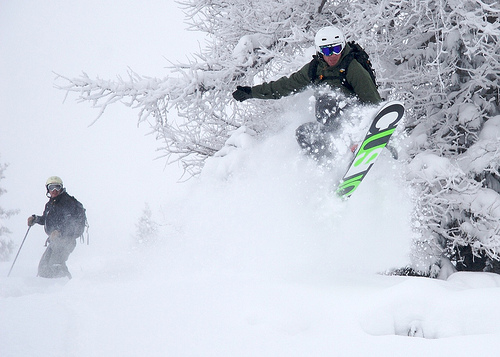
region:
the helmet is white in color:
[305, 24, 348, 58]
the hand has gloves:
[226, 78, 258, 109]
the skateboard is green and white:
[319, 107, 409, 209]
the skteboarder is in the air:
[219, 30, 414, 197]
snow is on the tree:
[391, 13, 484, 144]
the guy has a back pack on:
[40, 200, 98, 236]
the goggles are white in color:
[308, 41, 348, 68]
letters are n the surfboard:
[360, 104, 402, 189]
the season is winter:
[6, 8, 483, 350]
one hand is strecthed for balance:
[207, 34, 417, 199]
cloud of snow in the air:
[85, 87, 413, 327]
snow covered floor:
[0, 275, 496, 352]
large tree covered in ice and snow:
[56, 2, 498, 270]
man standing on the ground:
[10, 173, 90, 283]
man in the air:
[233, 28, 378, 168]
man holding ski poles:
[4, 177, 91, 281]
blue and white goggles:
[319, 44, 342, 54]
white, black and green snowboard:
[334, 102, 402, 204]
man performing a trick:
[233, 29, 378, 165]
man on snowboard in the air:
[230, 28, 402, 205]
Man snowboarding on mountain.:
[231, 21, 406, 206]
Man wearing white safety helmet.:
[311, 20, 349, 44]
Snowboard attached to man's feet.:
[335, 99, 406, 206]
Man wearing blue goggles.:
[318, 42, 349, 57]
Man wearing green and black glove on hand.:
[230, 83, 257, 100]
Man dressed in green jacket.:
[251, 42, 383, 103]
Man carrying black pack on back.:
[346, 37, 379, 87]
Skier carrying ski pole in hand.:
[4, 214, 39, 284]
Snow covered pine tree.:
[423, 16, 498, 268]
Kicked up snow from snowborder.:
[257, 87, 399, 263]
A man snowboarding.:
[225, 20, 410, 208]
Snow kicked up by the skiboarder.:
[195, 20, 455, 325]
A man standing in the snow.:
[25, 170, 90, 281]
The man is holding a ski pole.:
[0, 215, 35, 285]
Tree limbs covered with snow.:
[50, 0, 498, 280]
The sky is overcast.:
[0, 0, 250, 200]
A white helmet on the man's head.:
[310, 25, 350, 55]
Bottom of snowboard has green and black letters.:
[320, 95, 405, 210]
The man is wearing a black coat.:
[30, 195, 90, 240]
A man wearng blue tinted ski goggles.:
[315, 40, 340, 50]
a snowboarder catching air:
[230, 25, 400, 198]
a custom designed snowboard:
[338, 100, 405, 202]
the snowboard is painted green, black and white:
[337, 96, 407, 202]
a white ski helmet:
[313, 25, 343, 55]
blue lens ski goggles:
[317, 42, 343, 56]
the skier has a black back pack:
[338, 40, 377, 94]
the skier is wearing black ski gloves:
[231, 83, 254, 103]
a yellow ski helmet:
[43, 175, 65, 194]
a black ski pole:
[0, 213, 34, 289]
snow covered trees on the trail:
[404, 1, 499, 278]